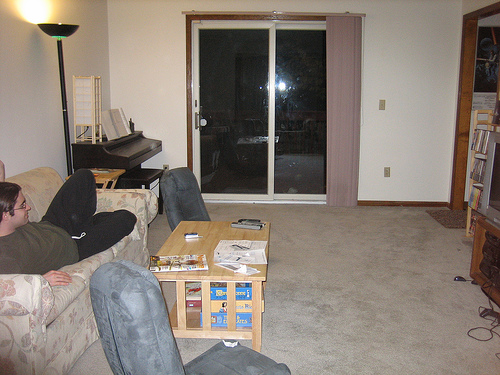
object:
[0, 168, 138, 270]
man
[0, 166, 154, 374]
couch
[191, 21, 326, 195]
door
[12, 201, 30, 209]
glasses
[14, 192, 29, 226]
face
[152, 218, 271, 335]
coffee table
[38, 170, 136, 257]
pants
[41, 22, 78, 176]
lamp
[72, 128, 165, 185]
piano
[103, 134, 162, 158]
lid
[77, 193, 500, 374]
carpet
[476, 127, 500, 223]
tv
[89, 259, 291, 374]
chair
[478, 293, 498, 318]
cords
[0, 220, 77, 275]
shirt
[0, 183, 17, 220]
hair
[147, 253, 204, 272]
magazine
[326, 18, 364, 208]
curtain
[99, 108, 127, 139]
sheet music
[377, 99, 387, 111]
power outlet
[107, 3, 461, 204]
wall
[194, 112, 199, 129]
handle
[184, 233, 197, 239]
cell phone